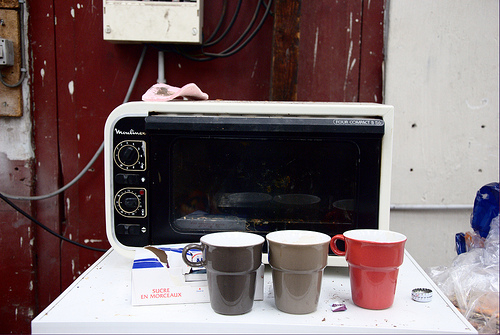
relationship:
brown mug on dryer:
[183, 231, 264, 316] [25, 230, 483, 331]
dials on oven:
[110, 133, 155, 222] [97, 93, 399, 264]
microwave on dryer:
[101, 99, 396, 267] [25, 230, 483, 331]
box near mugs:
[128, 239, 266, 308] [181, 225, 266, 315]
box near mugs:
[128, 239, 266, 308] [264, 226, 334, 316]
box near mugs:
[128, 239, 266, 308] [327, 226, 407, 307]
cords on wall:
[171, 0, 274, 62] [4, 0, 384, 333]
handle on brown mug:
[180, 239, 207, 269] [183, 231, 264, 316]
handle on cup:
[327, 231, 347, 258] [330, 225, 411, 312]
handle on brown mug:
[180, 243, 207, 269] [183, 217, 261, 304]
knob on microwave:
[110, 136, 148, 176] [98, 96, 396, 271]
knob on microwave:
[110, 182, 150, 222] [98, 96, 396, 271]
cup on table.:
[327, 228, 405, 311] [15, 229, 488, 334]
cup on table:
[327, 228, 405, 311] [88, 237, 415, 330]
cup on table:
[327, 228, 405, 311] [33, 192, 462, 334]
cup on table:
[327, 228, 405, 311] [32, 247, 478, 332]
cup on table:
[327, 228, 405, 311] [26, 234, 483, 333]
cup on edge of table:
[327, 228, 405, 311] [32, 247, 478, 332]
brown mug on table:
[183, 231, 264, 316] [26, 234, 483, 333]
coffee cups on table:
[264, 229, 332, 314] [26, 234, 483, 333]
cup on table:
[330, 225, 411, 312] [26, 234, 483, 333]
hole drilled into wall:
[408, 120, 421, 133] [386, 1, 497, 259]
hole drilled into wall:
[480, 118, 487, 131] [386, 1, 497, 259]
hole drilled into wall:
[406, 166, 416, 176] [386, 1, 497, 259]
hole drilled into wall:
[475, 166, 485, 175] [386, 1, 497, 259]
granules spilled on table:
[330, 304, 347, 314] [27, 242, 480, 328]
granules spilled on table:
[382, 315, 397, 329] [27, 242, 480, 328]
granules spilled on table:
[318, 313, 329, 323] [27, 242, 480, 328]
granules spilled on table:
[330, 277, 343, 291] [27, 242, 480, 328]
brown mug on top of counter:
[183, 231, 264, 316] [18, 210, 475, 333]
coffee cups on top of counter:
[264, 229, 332, 314] [18, 210, 475, 333]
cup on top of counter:
[330, 225, 411, 312] [18, 210, 475, 333]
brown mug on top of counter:
[183, 231, 264, 316] [31, 246, 475, 333]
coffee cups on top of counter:
[264, 229, 332, 314] [31, 246, 475, 333]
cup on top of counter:
[330, 225, 411, 312] [31, 246, 475, 333]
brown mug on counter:
[183, 231, 264, 316] [55, 183, 481, 333]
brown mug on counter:
[183, 231, 264, 316] [31, 246, 475, 333]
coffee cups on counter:
[264, 229, 332, 314] [31, 246, 475, 333]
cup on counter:
[330, 225, 411, 312] [31, 246, 475, 333]